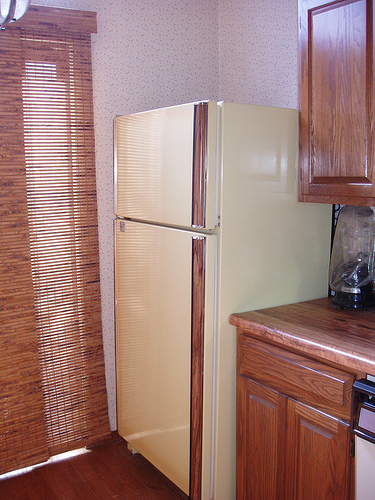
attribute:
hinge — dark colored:
[347, 435, 355, 460]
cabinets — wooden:
[297, 0, 374, 207]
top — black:
[351, 377, 372, 398]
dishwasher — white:
[351, 371, 374, 498]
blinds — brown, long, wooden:
[2, 3, 113, 478]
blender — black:
[328, 204, 374, 312]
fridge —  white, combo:
[91, 97, 303, 485]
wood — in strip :
[188, 236, 206, 498]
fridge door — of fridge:
[113, 217, 218, 499]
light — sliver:
[0, 448, 95, 479]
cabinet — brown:
[227, 296, 356, 499]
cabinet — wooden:
[294, 1, 373, 212]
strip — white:
[205, 102, 220, 432]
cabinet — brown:
[231, 338, 357, 498]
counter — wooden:
[225, 286, 373, 380]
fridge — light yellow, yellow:
[105, 99, 334, 496]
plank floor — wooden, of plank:
[95, 461, 124, 484]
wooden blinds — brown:
[14, 64, 89, 207]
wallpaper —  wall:
[219, 6, 297, 102]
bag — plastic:
[332, 207, 372, 288]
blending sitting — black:
[321, 188, 369, 326]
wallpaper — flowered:
[26, 0, 336, 431]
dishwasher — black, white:
[351, 375, 371, 498]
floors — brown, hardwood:
[15, 446, 147, 499]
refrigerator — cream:
[75, 117, 234, 287]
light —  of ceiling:
[1, 0, 33, 28]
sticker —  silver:
[118, 221, 126, 232]